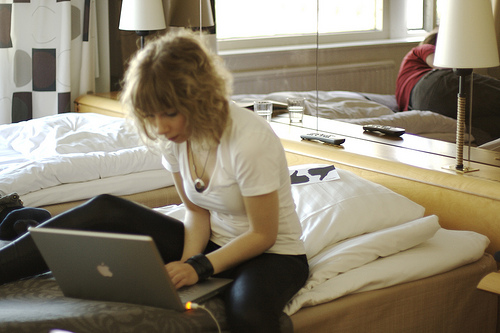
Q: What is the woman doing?
A: Sitting.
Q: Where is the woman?
A: On bed.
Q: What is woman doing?
A: Typing.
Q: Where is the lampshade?
A: On lamp.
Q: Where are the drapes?
A: On window.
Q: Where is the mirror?
A: Behind bed.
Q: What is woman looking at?
A: Computer.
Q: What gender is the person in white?
A: Female.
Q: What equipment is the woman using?
A: A laptop.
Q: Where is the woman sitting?
A: On a bed.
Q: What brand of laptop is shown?
A: An apple.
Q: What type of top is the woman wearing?
A: A V neck t-shirt.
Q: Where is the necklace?
A: Around the woman's neck.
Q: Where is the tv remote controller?
A: On the shelf behind the woman.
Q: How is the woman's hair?
A: Blonde and curly.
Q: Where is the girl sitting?
A: On a bed.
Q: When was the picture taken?
A: During daytime.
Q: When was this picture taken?
A: Daytime.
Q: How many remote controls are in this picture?
A: One.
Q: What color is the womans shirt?
A: White.